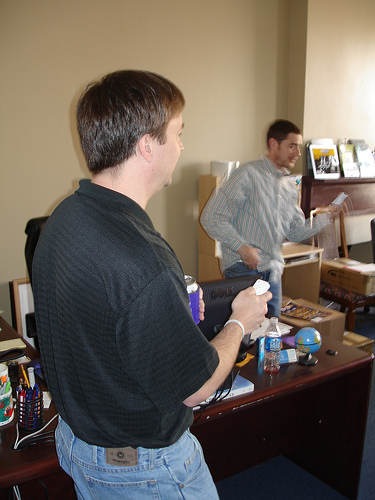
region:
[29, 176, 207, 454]
black colored collared shirt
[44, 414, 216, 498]
light colored blue jeans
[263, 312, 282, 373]
clear plastic water bottle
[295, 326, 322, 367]
small statue of a globe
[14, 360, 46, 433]
black container of pens and pencils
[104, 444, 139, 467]
logo of jeans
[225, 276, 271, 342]
small white Wii controller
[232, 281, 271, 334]
white hand of a man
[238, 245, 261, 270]
white hand of a man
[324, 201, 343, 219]
white hand of a man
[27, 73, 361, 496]
two mean playing a video game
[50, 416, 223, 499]
blue jeans of man wearing black shirt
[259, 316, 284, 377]
plastic water bottle on the desk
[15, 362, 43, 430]
pencil cup on the desk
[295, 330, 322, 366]
world globe on the desk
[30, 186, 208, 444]
black shirt of man playing video game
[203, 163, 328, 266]
striped button up shirt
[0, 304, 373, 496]
desk beside man playing video game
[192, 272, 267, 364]
black computer monitor on the desk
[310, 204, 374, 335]
chair with box in it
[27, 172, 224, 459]
the shirt is black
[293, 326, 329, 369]
a small blue globe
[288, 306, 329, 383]
a small blue globe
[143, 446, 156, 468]
belt loop on jeans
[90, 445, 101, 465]
belt loop on jeans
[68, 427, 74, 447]
belt loop on jeans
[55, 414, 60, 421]
belt loop on jeans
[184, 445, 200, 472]
small pocket on jeans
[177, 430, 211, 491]
small pocket on jeans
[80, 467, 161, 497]
small pocket on jeans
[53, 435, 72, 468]
small pocket on jeans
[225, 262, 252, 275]
small pocket on jeans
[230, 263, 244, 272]
small pocket on jeans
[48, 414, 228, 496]
Man wearing pants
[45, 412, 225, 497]
Man wearing blue pants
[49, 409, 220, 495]
Man is wearing pants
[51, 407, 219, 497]
Man is wearing blue pants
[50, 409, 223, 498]
Man wearing jeans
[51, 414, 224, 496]
Man wearing blue jeans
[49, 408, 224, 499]
Man is wearing jeans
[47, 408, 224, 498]
Man is wearing blue jeans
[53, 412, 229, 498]
Man wearing light blue jeans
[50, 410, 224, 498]
Man is wearing light blue jeans